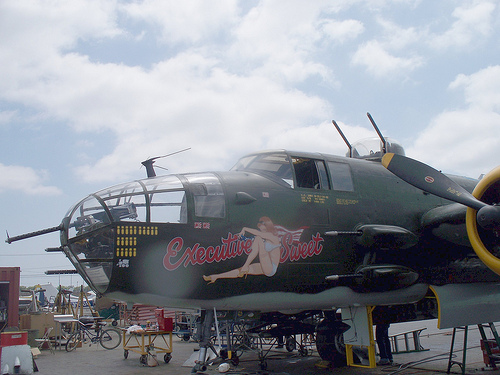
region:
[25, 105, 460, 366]
vintage fighter airplane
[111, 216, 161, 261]
symbols for enemy kills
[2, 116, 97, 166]
a patch of blue sky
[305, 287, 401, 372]
men working in the under-belly of a plane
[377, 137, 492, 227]
blade of a propeller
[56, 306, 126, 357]
bicycle at the air field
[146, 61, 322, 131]
clouds in the sky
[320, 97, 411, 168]
two barrels of a ball turret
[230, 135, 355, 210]
cockpit of the plane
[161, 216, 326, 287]
name and logo of the aircraft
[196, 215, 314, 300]
the woman is painted on the side of the helicopter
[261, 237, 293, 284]
the woman that is painted on the side of the helicopter is wearing a white bikini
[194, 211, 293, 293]
the woman that is painted on the side of the helicopter is wearing high heal shoes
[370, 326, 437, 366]
the latter is laying on the ground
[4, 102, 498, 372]
the helicopter is black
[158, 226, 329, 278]
the helicopter has red words on it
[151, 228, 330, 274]
the red words say executive sweet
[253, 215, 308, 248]
the woman painted on the helicopter has an american flag behind her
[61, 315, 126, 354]
the bicycle is parked beside the helicopter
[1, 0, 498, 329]
the sky is cloudy and blue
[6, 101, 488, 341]
World War II B-17 aircraft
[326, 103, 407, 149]
Machine guns on an aircraft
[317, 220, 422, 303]
Machine guns on the side of an aircraft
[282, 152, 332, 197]
Window of an aircraft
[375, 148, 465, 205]
Propeller blade of an aircraft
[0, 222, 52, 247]
Gun barrel of a machine gun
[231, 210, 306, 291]
Painting on the side of an aircraft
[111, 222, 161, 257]
Bombs painted on the side of a plane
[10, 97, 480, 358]
World War II bomber on display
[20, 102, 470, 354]
Bomber at an air show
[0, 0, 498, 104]
sky filled with white clouds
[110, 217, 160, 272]
design on side of aircraft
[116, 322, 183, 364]
yellow metal cart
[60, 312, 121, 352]
bicycle parked beside plane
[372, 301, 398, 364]
person standing under aircraft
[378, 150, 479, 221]
grey and yellow plane propeller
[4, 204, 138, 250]
machine gun on front of aircraft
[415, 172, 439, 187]
small design on propeller of plane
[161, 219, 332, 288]
large design on woman on side of aircraft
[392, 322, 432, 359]
silver metal ladder laying on ground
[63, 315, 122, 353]
bike in the parking lot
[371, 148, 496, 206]
propeller on the plane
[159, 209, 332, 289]
Name of the plane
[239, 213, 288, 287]
Girl painted on the side of the plane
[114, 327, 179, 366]
yellow cart with wheels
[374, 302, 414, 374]
bottom half of the mechanic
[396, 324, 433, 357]
ladder laying on the ground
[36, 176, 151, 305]
front nose of the plane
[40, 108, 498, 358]
A parked plane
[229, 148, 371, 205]
cockpit area of the plane